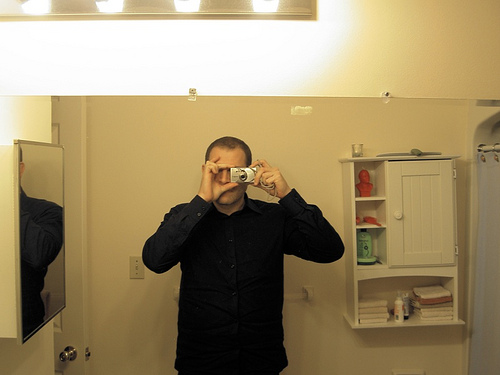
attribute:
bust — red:
[355, 171, 377, 200]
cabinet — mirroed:
[11, 137, 81, 344]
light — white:
[126, 0, 338, 34]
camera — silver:
[230, 166, 258, 184]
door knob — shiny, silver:
[57, 345, 79, 367]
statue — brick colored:
[353, 168, 385, 196]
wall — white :
[0, 17, 499, 93]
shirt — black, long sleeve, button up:
[141, 189, 343, 369]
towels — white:
[361, 297, 395, 327]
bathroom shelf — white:
[343, 156, 469, 329]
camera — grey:
[215, 156, 282, 188]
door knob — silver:
[58, 341, 80, 369]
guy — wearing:
[132, 137, 320, 362]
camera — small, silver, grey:
[222, 163, 263, 187]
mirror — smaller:
[16, 142, 66, 337]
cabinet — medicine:
[0, 140, 65, 343]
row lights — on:
[20, 1, 308, 28]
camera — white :
[227, 162, 265, 187]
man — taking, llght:
[137, 134, 345, 374]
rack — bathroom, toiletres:
[338, 150, 468, 332]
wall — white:
[108, 108, 160, 169]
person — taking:
[138, 133, 348, 373]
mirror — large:
[16, 148, 78, 329]